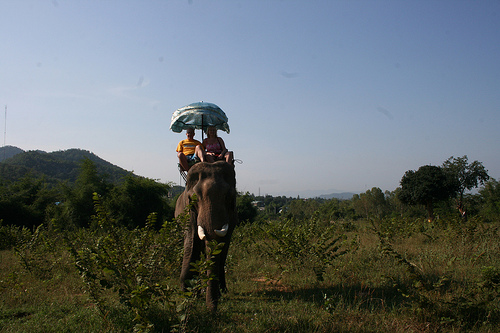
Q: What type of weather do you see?
A: It is clear.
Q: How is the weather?
A: It is clear.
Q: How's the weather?
A: It is clear.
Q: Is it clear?
A: Yes, it is clear.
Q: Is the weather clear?
A: Yes, it is clear.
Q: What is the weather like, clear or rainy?
A: It is clear.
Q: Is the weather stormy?
A: No, it is clear.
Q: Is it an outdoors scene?
A: Yes, it is outdoors.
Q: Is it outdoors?
A: Yes, it is outdoors.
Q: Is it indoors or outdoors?
A: It is outdoors.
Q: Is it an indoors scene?
A: No, it is outdoors.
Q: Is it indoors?
A: No, it is outdoors.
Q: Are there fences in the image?
A: No, there are no fences.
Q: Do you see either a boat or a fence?
A: No, there are no fences or boats.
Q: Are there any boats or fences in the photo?
A: No, there are no fences or boats.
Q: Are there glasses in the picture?
A: No, there are no glasses.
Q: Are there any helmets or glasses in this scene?
A: No, there are no glasses or helmets.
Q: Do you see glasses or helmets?
A: No, there are no glasses or helmets.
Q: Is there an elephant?
A: Yes, there is an elephant.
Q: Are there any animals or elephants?
A: Yes, there is an elephant.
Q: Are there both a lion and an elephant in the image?
A: No, there is an elephant but no lions.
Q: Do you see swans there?
A: No, there are no swans.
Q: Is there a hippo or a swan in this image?
A: No, there are no swans or hippos.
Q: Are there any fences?
A: No, there are no fences.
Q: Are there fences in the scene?
A: No, there are no fences.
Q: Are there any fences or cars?
A: No, there are no fences or cars.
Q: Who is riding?
A: The people are riding.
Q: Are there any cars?
A: No, there are no cars.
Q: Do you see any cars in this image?
A: No, there are no cars.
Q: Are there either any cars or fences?
A: No, there are no cars or fences.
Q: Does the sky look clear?
A: Yes, the sky is clear.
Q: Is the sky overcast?
A: No, the sky is clear.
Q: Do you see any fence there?
A: No, there are no fences.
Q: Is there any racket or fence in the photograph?
A: No, there are no fences or rackets.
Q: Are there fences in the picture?
A: No, there are no fences.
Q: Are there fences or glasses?
A: No, there are no fences or glasses.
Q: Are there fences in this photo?
A: No, there are no fences.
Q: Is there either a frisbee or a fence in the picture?
A: No, there are no fences or frisbees.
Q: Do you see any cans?
A: No, there are no cans.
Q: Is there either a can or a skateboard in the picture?
A: No, there are no cans or skateboards.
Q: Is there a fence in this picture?
A: No, there are no fences.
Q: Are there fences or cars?
A: No, there are no fences or cars.